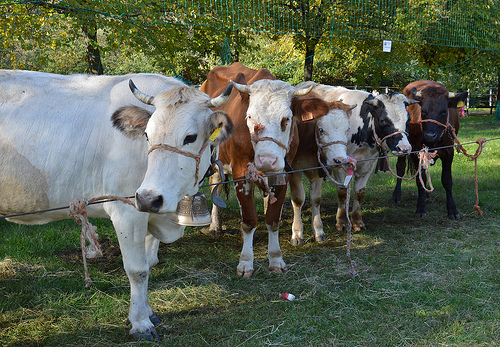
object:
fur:
[202, 62, 301, 169]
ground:
[0, 108, 497, 347]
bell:
[174, 195, 213, 227]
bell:
[271, 172, 287, 186]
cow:
[199, 62, 330, 277]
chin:
[135, 203, 179, 214]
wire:
[0, 134, 499, 347]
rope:
[243, 162, 277, 205]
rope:
[313, 147, 357, 277]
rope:
[382, 144, 434, 192]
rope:
[416, 106, 486, 215]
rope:
[71, 195, 135, 288]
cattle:
[0, 69, 233, 342]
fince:
[0, 0, 497, 64]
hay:
[290, 231, 471, 309]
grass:
[0, 226, 500, 347]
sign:
[382, 39, 392, 53]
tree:
[255, 0, 432, 81]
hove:
[128, 324, 163, 342]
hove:
[236, 262, 291, 279]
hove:
[291, 230, 330, 248]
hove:
[336, 217, 367, 232]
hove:
[414, 206, 462, 219]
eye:
[182, 132, 199, 146]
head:
[109, 77, 233, 215]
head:
[228, 79, 313, 173]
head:
[300, 98, 359, 168]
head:
[364, 92, 421, 158]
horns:
[128, 79, 154, 107]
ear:
[109, 104, 151, 138]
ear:
[209, 110, 233, 144]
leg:
[99, 184, 163, 341]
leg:
[233, 177, 258, 278]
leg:
[265, 176, 290, 274]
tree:
[0, 1, 215, 74]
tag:
[209, 127, 222, 141]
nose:
[133, 189, 164, 212]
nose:
[254, 152, 282, 168]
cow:
[289, 90, 358, 247]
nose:
[332, 155, 350, 167]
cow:
[291, 81, 421, 232]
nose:
[391, 140, 412, 155]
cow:
[392, 79, 468, 218]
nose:
[422, 131, 437, 141]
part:
[294, 0, 346, 79]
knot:
[66, 199, 87, 223]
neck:
[122, 153, 209, 220]